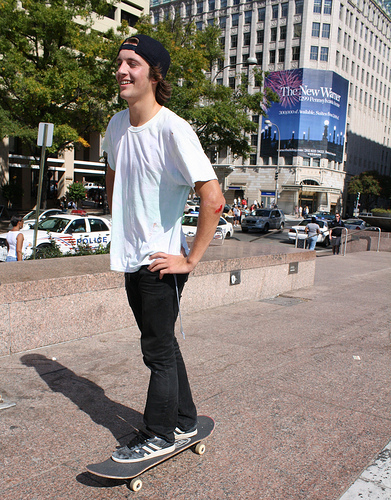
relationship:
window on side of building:
[307, 45, 330, 63] [149, 1, 390, 218]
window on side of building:
[309, 20, 332, 41] [149, 1, 390, 218]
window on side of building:
[291, 22, 305, 40] [149, 1, 390, 218]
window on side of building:
[290, 44, 302, 64] [149, 1, 390, 218]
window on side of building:
[277, 25, 287, 42] [149, 1, 390, 218]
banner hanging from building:
[258, 68, 348, 164] [149, 1, 390, 218]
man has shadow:
[100, 35, 226, 464] [21, 351, 143, 449]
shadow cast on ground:
[21, 351, 143, 449] [2, 251, 389, 498]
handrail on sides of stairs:
[304, 226, 349, 255] [311, 247, 365, 265]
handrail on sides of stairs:
[250, 226, 299, 249] [311, 247, 365, 265]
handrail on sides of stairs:
[346, 225, 382, 252] [311, 247, 365, 265]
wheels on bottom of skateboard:
[127, 441, 204, 491] [85, 411, 214, 491]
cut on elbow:
[212, 204, 224, 215] [201, 194, 227, 218]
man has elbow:
[100, 35, 226, 464] [201, 194, 227, 218]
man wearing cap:
[100, 35, 226, 464] [117, 31, 170, 81]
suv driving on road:
[239, 205, 285, 234] [176, 220, 390, 259]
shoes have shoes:
[112, 422, 196, 464] [111, 422, 197, 463]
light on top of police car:
[69, 207, 85, 215] [1, 208, 112, 260]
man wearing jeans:
[100, 35, 226, 464] [122, 264, 198, 443]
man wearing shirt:
[100, 35, 226, 464] [99, 105, 218, 274]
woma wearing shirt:
[303, 216, 320, 253] [306, 222, 319, 238]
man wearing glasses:
[326, 211, 344, 258] [334, 212, 342, 220]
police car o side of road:
[1, 208, 112, 260] [176, 220, 390, 259]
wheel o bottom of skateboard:
[128, 477, 143, 493] [85, 411, 214, 491]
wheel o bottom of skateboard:
[195, 441, 207, 455] [85, 411, 214, 491]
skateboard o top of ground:
[85, 411, 214, 491] [2, 251, 389, 498]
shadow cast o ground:
[21, 351, 143, 449] [2, 251, 389, 498]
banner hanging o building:
[258, 68, 348, 164] [149, 1, 390, 218]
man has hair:
[100, 35, 226, 464] [148, 63, 174, 106]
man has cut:
[100, 35, 226, 464] [212, 204, 224, 215]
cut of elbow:
[212, 204, 224, 215] [201, 194, 227, 218]